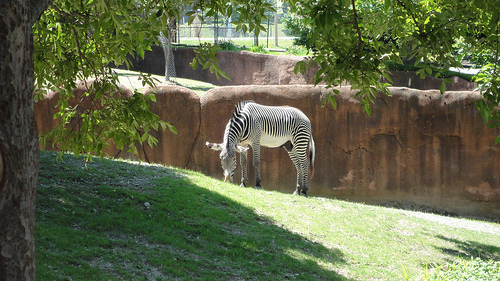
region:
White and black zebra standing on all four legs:
[201, 90, 321, 197]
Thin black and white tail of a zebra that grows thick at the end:
[303, 133, 318, 178]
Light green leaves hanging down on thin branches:
[44, 7, 164, 151]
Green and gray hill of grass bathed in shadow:
[80, 169, 186, 258]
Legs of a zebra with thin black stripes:
[233, 141, 310, 194]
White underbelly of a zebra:
[255, 134, 289, 148]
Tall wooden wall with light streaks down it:
[323, 81, 470, 206]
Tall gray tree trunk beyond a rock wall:
[148, 21, 183, 77]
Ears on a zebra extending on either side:
[205, 136, 253, 161]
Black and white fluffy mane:
[221, 101, 240, 148]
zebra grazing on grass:
[201, 90, 356, 215]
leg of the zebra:
[242, 140, 267, 194]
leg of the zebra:
[237, 156, 249, 191]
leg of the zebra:
[299, 164, 311, 195]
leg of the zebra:
[288, 168, 303, 199]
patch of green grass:
[198, 222, 214, 237]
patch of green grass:
[138, 228, 153, 247]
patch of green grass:
[292, 249, 317, 270]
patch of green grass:
[260, 224, 275, 239]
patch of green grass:
[111, 183, 127, 195]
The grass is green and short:
[62, 193, 357, 262]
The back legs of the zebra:
[283, 149, 311, 192]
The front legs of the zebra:
[236, 151, 266, 188]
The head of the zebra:
[204, 130, 248, 185]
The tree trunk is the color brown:
[2, 10, 42, 279]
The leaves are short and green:
[51, 18, 147, 133]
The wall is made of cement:
[341, 99, 469, 195]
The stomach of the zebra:
[261, 104, 290, 149]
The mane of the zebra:
[213, 96, 258, 153]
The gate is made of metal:
[177, 12, 282, 47]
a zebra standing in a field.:
[198, 92, 345, 193]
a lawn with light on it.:
[149, 162, 499, 279]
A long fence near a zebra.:
[24, 88, 499, 228]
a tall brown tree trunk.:
[1, 0, 48, 268]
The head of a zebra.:
[194, 103, 242, 190]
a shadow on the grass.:
[424, 223, 497, 277]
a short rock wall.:
[137, 37, 477, 107]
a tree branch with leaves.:
[27, 70, 184, 178]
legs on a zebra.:
[280, 130, 327, 202]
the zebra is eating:
[205, 91, 363, 226]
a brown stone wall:
[138, 56, 262, 168]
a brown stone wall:
[318, 76, 390, 196]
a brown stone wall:
[382, 71, 499, 204]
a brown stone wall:
[229, 43, 289, 85]